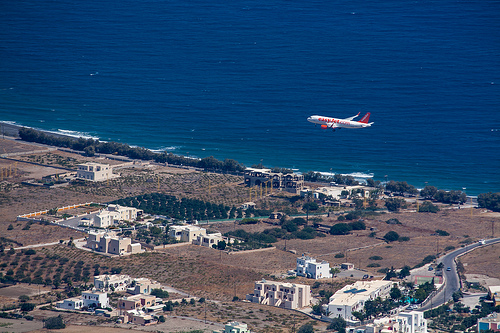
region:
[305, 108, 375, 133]
Easy jet plane in flight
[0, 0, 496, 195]
Plane flying over the coastline.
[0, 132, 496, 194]
Coastline with scattered buildings.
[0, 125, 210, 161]
Treeline along a coast highway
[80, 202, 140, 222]
White resort buildings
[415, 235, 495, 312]
Cars driving on an s-curve road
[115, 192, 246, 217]
Small orchard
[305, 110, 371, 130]
Orange and white airplane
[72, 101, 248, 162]
Mediterranean coastline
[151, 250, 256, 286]
Hill covered in brown grass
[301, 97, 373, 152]
red and white airplane in air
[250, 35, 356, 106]
dark blue water is under airplane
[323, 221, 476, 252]
dark brown fields on ground under airplane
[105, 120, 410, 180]
white waves crashing on shore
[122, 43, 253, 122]
few waves are on water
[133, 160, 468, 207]
line of green trees near shore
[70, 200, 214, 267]
large cluster of white buildings on ground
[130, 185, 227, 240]
many green trees behind cluster of buildings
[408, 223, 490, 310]
grey road curls around on right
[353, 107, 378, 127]
plane in air has red tail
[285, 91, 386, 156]
A side view of an airplane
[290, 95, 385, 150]
The airplane is white in color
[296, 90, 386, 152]
Airplane is flying in the air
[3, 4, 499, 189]
Water is blue in color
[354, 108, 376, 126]
Tail of the airplane is red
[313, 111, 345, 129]
Red wording is on the side of the airplane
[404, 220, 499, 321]
A curvy road in the distance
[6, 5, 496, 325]
Photo was taken in the daytime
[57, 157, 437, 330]
Buildings are on the ground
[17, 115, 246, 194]
Trees are near the water shore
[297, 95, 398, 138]
A plane flying above the ground.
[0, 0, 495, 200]
The water in the ocean.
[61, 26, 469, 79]
The water is blue.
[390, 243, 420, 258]
Dirt on the ground.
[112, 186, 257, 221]
A grove of trees.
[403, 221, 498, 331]
A street with a car on it.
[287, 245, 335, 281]
The building is white.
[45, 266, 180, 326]
A group of buildings clustered together.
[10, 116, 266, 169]
Trees near the shore.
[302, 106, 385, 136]
The plane is white and red.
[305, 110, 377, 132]
White and red airplane.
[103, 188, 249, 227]
Rectangular area of shrubbery.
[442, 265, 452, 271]
Blue car driving on the road.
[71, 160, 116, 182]
A large white building.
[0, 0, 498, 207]
A large body of water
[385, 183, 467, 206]
Tree's along the water line.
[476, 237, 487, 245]
Light colored vehical along the road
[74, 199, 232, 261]
Cluster of white buildings.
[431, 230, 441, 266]
Poles near the side of the road.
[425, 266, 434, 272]
Small blue car near the side of the road.